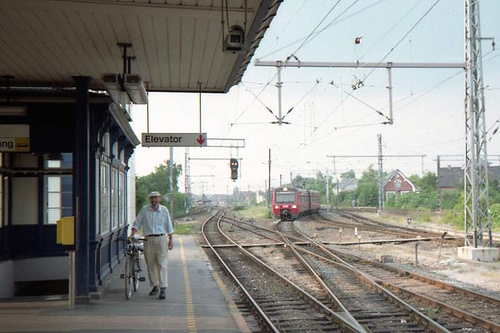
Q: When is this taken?
A: Daytime.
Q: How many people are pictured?
A: One.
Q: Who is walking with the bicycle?
A: A man.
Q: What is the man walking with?
A: A bicycle.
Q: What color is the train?
A: Red.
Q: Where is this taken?
A: A train station.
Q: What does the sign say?
A: Elevator.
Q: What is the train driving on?
A: Train tracks.